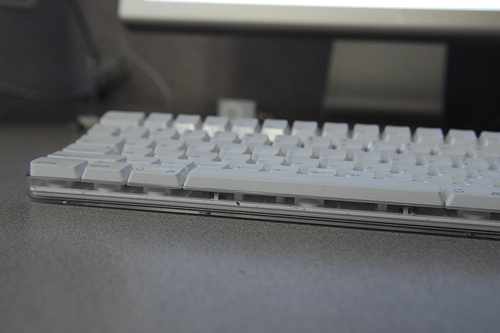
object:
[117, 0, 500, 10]
computer screen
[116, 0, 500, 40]
bottom edge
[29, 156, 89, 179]
key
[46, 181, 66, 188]
pad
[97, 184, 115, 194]
pad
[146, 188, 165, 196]
pad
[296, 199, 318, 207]
pad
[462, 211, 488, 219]
pad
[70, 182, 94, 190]
space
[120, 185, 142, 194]
space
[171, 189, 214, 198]
space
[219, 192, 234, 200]
space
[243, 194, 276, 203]
space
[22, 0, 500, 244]
computer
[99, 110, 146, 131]
keys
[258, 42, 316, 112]
wall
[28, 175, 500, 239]
panel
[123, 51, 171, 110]
wires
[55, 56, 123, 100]
wires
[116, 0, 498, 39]
computer monitor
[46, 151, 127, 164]
shift key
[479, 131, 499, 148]
key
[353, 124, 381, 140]
key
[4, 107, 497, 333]
desk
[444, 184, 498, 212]
bar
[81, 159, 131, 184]
bar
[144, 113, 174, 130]
keys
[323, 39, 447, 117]
stand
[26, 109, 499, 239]
keyboard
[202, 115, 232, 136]
key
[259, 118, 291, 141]
key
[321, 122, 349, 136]
key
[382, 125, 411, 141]
key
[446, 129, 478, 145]
key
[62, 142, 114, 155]
tab key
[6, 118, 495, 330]
surface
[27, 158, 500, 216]
bottom row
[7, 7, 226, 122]
background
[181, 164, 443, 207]
space bar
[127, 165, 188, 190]
button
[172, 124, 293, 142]
light